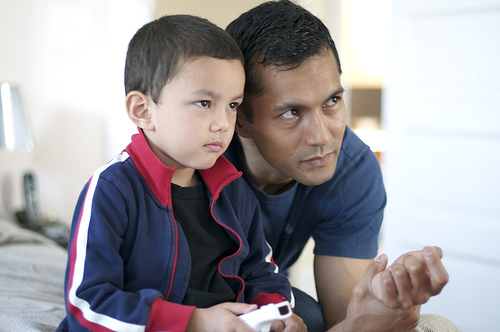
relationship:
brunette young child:
[146, 27, 228, 53] [71, 14, 251, 330]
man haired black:
[218, 3, 457, 315] [255, 11, 297, 37]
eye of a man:
[280, 107, 300, 123] [218, 3, 457, 315]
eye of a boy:
[190, 95, 213, 110] [71, 14, 251, 330]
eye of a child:
[190, 95, 213, 110] [54, 14, 314, 332]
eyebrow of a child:
[196, 89, 244, 104] [54, 14, 314, 332]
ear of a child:
[121, 88, 157, 134] [54, 14, 314, 332]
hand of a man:
[352, 240, 446, 323] [218, 3, 457, 315]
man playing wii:
[218, 3, 457, 315] [217, 284, 288, 328]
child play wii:
[54, 14, 314, 332] [217, 284, 288, 328]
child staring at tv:
[54, 14, 314, 332] [461, 16, 499, 267]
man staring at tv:
[218, 3, 457, 315] [461, 16, 499, 267]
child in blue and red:
[54, 14, 314, 332] [122, 151, 172, 222]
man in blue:
[218, 3, 457, 315] [333, 189, 376, 220]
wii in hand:
[217, 284, 288, 328] [352, 240, 446, 323]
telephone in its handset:
[12, 170, 73, 248] [16, 208, 78, 247]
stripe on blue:
[73, 148, 132, 297] [105, 211, 136, 249]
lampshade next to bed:
[0, 83, 35, 152] [4, 217, 64, 326]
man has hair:
[218, 3, 457, 315] [254, 13, 298, 57]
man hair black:
[218, 3, 457, 315] [255, 11, 297, 37]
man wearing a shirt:
[218, 3, 457, 315] [245, 159, 390, 319]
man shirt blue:
[218, 3, 457, 315] [333, 189, 376, 220]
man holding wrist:
[218, 3, 457, 315] [352, 240, 446, 323]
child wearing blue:
[54, 14, 314, 332] [105, 211, 136, 249]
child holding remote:
[54, 14, 314, 332] [217, 284, 288, 328]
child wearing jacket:
[54, 14, 314, 332] [76, 139, 293, 332]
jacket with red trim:
[76, 139, 293, 332] [126, 133, 177, 207]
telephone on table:
[12, 175, 77, 251] [56, 202, 88, 274]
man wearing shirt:
[218, 3, 457, 315] [245, 159, 390, 319]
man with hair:
[218, 3, 457, 315] [254, 13, 298, 57]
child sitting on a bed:
[54, 14, 314, 332] [4, 217, 64, 326]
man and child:
[218, 3, 457, 315] [71, 14, 251, 330]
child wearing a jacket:
[71, 14, 251, 330] [76, 139, 293, 332]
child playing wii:
[71, 14, 251, 330] [217, 284, 288, 328]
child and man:
[71, 14, 251, 330] [218, 3, 457, 315]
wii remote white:
[217, 284, 288, 328] [258, 313, 268, 320]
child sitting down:
[71, 14, 251, 330] [25, 281, 125, 329]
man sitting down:
[218, 3, 457, 315] [298, 282, 349, 330]